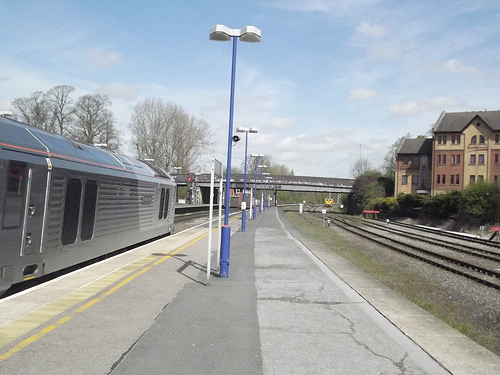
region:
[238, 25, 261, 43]
street light on a blue pole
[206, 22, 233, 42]
street light on a blue pole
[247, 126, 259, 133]
street light on a blue pole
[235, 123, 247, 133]
street light on a blue pole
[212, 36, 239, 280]
blue metal pole near train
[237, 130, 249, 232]
blue metal pole near train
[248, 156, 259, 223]
blue metal pole near train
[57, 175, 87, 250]
window on a train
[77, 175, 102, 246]
window on a train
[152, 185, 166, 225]
window on a train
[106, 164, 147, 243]
train is silver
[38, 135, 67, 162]
red stripe on top of train car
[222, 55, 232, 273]
blue light pole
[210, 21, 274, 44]
two lights on one pole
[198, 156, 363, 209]
bridge over the train tracks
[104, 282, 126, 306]
yellow line on platform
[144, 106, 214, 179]
trees on other side of bridge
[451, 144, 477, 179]
building with tan and brown colors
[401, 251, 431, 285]
gravel next to tracks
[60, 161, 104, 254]
windows on the train car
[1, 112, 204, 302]
train on the tracks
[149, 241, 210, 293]
shadow on the ground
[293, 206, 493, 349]
sporadic patches of grass growing by the tracks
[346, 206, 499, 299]
parallel sets of train tracks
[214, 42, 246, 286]
skinny blue pole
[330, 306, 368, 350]
crack in the concrete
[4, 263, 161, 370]
faded yellow line on the ground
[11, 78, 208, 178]
trees with no leaves on them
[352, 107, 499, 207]
brown building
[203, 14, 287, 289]
row of lamp posts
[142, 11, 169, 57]
this is the sky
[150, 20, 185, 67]
the sky is blue in color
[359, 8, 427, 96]
the sky has some clouds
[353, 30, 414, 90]
the clouds are white in color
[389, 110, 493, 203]
this is a building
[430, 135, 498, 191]
the building has several windows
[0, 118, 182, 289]
this is a train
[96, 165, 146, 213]
the train is grey in color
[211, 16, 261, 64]
this is a street light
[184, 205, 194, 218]
this is a railway line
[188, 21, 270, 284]
lights on a blue pole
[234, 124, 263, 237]
lights on a blue pole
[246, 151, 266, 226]
lights on a blue pole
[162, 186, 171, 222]
window on a train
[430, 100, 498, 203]
building near the tracks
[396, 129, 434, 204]
building near the tracks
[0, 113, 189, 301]
train on the train tracks